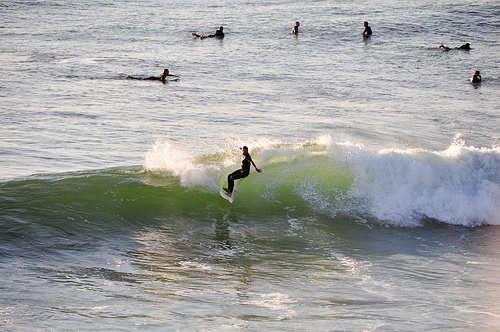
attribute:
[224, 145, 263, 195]
man — waking, surfing, standing, wet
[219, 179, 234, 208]
surfboard — white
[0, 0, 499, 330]
water — green, calm, splashing, white, rippling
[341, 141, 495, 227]
wave — white, large, exsisting, spraying, splashing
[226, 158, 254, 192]
wetsuit — black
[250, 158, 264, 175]
arms — extended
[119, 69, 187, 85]
person — swimming, floating